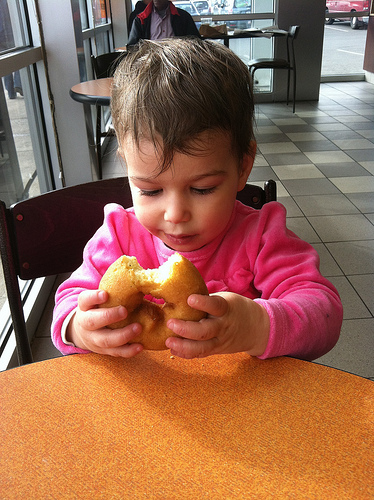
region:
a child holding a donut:
[35, 30, 353, 437]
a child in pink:
[49, 30, 354, 434]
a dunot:
[89, 242, 210, 360]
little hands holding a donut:
[60, 247, 263, 367]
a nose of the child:
[163, 189, 191, 225]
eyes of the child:
[126, 181, 219, 202]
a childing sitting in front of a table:
[25, 28, 350, 412]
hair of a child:
[152, 78, 209, 136]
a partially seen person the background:
[108, 0, 216, 34]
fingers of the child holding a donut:
[80, 285, 149, 366]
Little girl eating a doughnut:
[67, 40, 336, 384]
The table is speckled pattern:
[73, 412, 269, 496]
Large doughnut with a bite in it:
[95, 250, 229, 356]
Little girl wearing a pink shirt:
[60, 205, 343, 405]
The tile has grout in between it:
[316, 218, 372, 284]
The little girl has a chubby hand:
[173, 293, 276, 363]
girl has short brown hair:
[109, 32, 269, 165]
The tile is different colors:
[260, 114, 365, 217]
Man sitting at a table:
[122, 6, 221, 42]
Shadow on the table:
[204, 394, 361, 476]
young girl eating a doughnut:
[50, 37, 342, 361]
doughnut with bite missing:
[91, 250, 209, 351]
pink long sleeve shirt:
[48, 201, 344, 361]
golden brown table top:
[4, 345, 372, 495]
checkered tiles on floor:
[276, 87, 366, 237]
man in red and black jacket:
[126, 0, 204, 41]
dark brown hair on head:
[107, 35, 261, 182]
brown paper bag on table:
[196, 21, 230, 38]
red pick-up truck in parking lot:
[322, 2, 371, 28]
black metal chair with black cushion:
[244, 23, 301, 115]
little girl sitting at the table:
[26, 37, 331, 367]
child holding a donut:
[55, 230, 262, 379]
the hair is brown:
[65, 33, 265, 162]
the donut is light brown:
[82, 236, 196, 359]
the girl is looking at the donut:
[30, 20, 306, 369]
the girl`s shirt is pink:
[38, 200, 349, 371]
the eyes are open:
[119, 164, 229, 204]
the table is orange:
[3, 360, 332, 473]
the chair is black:
[3, 178, 278, 359]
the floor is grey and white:
[302, 71, 372, 215]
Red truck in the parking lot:
[323, 0, 372, 28]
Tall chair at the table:
[247, 24, 298, 114]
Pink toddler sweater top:
[51, 201, 344, 362]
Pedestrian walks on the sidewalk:
[0, 6, 28, 100]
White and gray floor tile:
[254, 81, 372, 207]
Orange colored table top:
[1, 348, 372, 489]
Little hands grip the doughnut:
[73, 249, 258, 359]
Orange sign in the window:
[97, 0, 109, 20]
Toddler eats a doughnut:
[50, 34, 342, 360]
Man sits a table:
[125, 0, 203, 46]